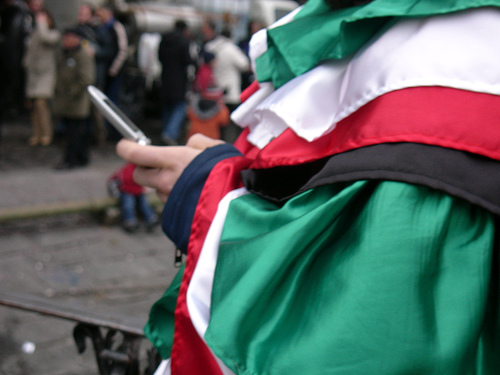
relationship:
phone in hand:
[87, 84, 154, 145] [117, 133, 227, 205]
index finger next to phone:
[115, 138, 183, 168] [87, 84, 154, 145]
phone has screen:
[87, 84, 154, 145] [103, 97, 140, 133]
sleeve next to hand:
[162, 141, 244, 255] [117, 133, 227, 205]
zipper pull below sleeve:
[174, 246, 183, 268] [162, 141, 244, 255]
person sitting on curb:
[108, 159, 160, 235] [0, 192, 165, 231]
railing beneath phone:
[0, 291, 163, 374] [87, 84, 154, 145]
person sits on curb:
[108, 159, 160, 235] [0, 192, 165, 231]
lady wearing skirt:
[23, 9, 62, 148] [26, 66, 57, 97]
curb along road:
[0, 192, 165, 231] [1, 218, 187, 374]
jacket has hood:
[187, 97, 230, 141] [193, 96, 219, 121]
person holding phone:
[116, 1, 500, 374] [87, 84, 154, 145]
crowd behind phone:
[1, 1, 268, 173] [87, 84, 154, 145]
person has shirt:
[108, 159, 160, 235] [108, 163, 144, 194]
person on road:
[116, 1, 500, 374] [1, 218, 187, 374]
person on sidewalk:
[53, 28, 100, 168] [1, 109, 172, 210]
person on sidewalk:
[158, 20, 191, 146] [1, 109, 172, 210]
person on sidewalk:
[93, 5, 129, 143] [1, 109, 172, 210]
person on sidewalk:
[201, 26, 250, 146] [1, 109, 172, 210]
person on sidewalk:
[65, 4, 97, 44] [1, 109, 172, 210]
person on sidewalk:
[237, 18, 267, 91] [1, 109, 172, 210]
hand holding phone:
[117, 133, 227, 205] [87, 84, 154, 145]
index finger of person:
[115, 138, 183, 168] [116, 1, 500, 374]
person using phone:
[116, 1, 500, 374] [87, 84, 154, 145]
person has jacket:
[184, 81, 230, 140] [187, 97, 230, 141]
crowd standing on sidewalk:
[1, 1, 268, 173] [1, 109, 172, 210]